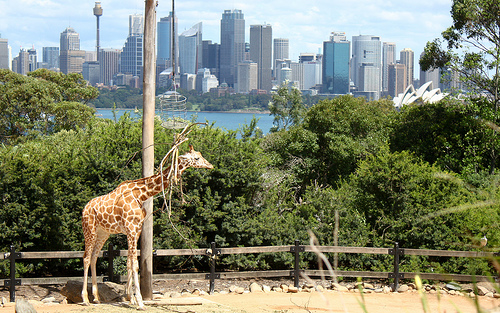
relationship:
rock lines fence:
[39, 289, 61, 306] [3, 241, 497, 288]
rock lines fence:
[228, 277, 245, 296] [3, 241, 497, 288]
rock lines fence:
[247, 279, 260, 291] [3, 241, 497, 288]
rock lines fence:
[393, 280, 410, 295] [3, 241, 497, 288]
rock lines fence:
[472, 281, 496, 292] [3, 241, 497, 288]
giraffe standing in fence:
[80, 145, 212, 309] [0, 241, 500, 301]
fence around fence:
[225, 235, 359, 281] [0, 241, 500, 301]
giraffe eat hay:
[80, 145, 213, 311] [154, 122, 191, 207]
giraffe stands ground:
[80, 145, 212, 309] [2, 290, 499, 312]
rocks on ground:
[231, 277, 295, 293] [5, 265, 499, 312]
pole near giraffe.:
[140, 53, 162, 166] [71, 142, 215, 310]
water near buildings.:
[0, 108, 304, 141] [36, 17, 410, 116]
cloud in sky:
[340, 0, 414, 32] [0, 1, 497, 81]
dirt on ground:
[0, 291, 500, 312] [16, 276, 496, 311]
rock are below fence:
[396, 282, 408, 292] [1, 243, 497, 300]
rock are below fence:
[249, 280, 260, 292] [1, 243, 497, 300]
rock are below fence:
[197, 289, 208, 298] [1, 243, 497, 300]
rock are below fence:
[314, 284, 324, 293] [1, 243, 497, 300]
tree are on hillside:
[24, 121, 118, 208] [4, 132, 479, 240]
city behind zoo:
[7, 8, 485, 98] [10, 89, 485, 298]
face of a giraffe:
[188, 139, 209, 188] [63, 135, 205, 310]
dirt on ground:
[234, 284, 289, 311] [175, 279, 206, 310]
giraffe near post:
[80, 145, 212, 309] [137, 0, 154, 299]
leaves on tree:
[425, 46, 454, 73] [415, 1, 498, 138]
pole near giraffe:
[140, 0, 154, 300] [74, 139, 222, 306]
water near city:
[94, 101, 291, 142] [10, 10, 444, 134]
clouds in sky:
[313, 4, 459, 59] [298, 10, 360, 35]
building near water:
[323, 41, 349, 93] [79, 105, 338, 139]